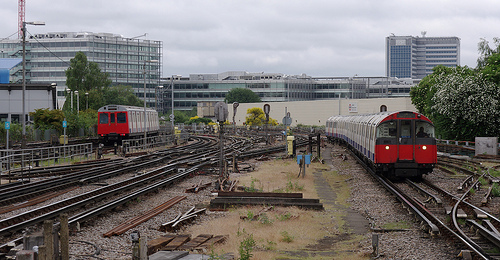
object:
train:
[95, 103, 161, 137]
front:
[96, 105, 128, 137]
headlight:
[385, 144, 391, 150]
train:
[324, 111, 440, 179]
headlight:
[422, 145, 428, 150]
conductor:
[417, 126, 430, 138]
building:
[382, 35, 460, 76]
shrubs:
[33, 108, 99, 141]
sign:
[296, 154, 312, 165]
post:
[299, 155, 306, 179]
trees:
[410, 37, 500, 144]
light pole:
[17, 20, 33, 143]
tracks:
[0, 146, 247, 258]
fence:
[0, 138, 94, 164]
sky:
[0, 2, 500, 45]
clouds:
[166, 2, 375, 53]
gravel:
[136, 196, 158, 209]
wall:
[228, 96, 424, 128]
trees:
[59, 50, 140, 108]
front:
[374, 110, 440, 179]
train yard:
[1, 120, 499, 259]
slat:
[123, 194, 191, 238]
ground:
[0, 126, 500, 259]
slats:
[210, 190, 308, 198]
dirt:
[234, 218, 369, 259]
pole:
[285, 135, 296, 156]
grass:
[238, 233, 256, 258]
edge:
[131, 111, 159, 132]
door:
[396, 118, 417, 161]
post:
[169, 73, 180, 130]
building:
[0, 32, 162, 108]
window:
[203, 82, 210, 90]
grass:
[490, 167, 500, 178]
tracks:
[362, 171, 500, 257]